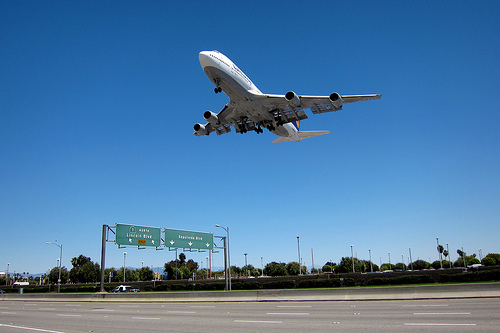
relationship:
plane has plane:
[193, 46, 381, 145] [190, 49, 382, 143]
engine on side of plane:
[286, 89, 301, 107] [193, 46, 381, 145]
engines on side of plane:
[328, 92, 342, 110] [193, 46, 381, 145]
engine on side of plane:
[204, 110, 217, 125] [193, 46, 381, 145]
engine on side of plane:
[193, 123, 206, 135] [193, 46, 381, 145]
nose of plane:
[197, 49, 209, 64] [193, 46, 381, 145]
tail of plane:
[270, 127, 330, 146] [193, 46, 381, 145]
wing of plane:
[262, 91, 381, 112] [193, 46, 381, 145]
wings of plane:
[191, 101, 250, 137] [193, 46, 381, 145]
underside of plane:
[196, 62, 375, 145] [193, 46, 381, 145]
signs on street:
[115, 222, 214, 252] [2, 287, 498, 331]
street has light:
[2, 287, 498, 331] [214, 223, 232, 290]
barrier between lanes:
[1, 288, 498, 301] [2, 287, 498, 331]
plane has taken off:
[193, 46, 381, 145] [195, 48, 382, 146]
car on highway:
[112, 284, 137, 292] [2, 287, 498, 331]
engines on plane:
[194, 89, 341, 136] [193, 46, 381, 145]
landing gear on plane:
[238, 116, 286, 133] [193, 46, 381, 145]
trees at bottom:
[51, 253, 499, 284] [1, 255, 498, 332]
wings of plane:
[192, 91, 380, 136] [193, 46, 381, 145]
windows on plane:
[210, 49, 222, 55] [193, 46, 381, 145]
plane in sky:
[193, 46, 381, 145] [0, 1, 497, 273]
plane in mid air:
[193, 46, 381, 145] [0, 1, 497, 273]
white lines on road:
[225, 303, 314, 327] [2, 287, 498, 331]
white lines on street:
[225, 303, 314, 327] [2, 287, 498, 331]